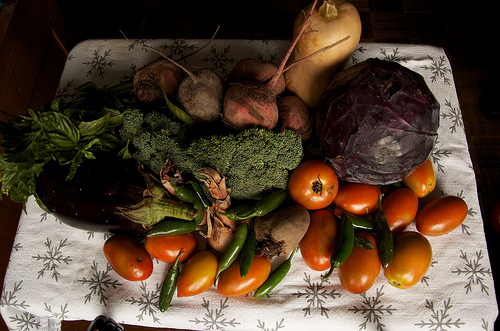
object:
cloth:
[0, 38, 497, 329]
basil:
[39, 109, 81, 152]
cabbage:
[317, 57, 440, 184]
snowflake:
[31, 236, 74, 282]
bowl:
[36, 152, 143, 235]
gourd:
[283, 0, 362, 109]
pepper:
[320, 211, 355, 278]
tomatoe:
[414, 194, 469, 236]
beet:
[223, 7, 316, 129]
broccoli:
[188, 126, 304, 201]